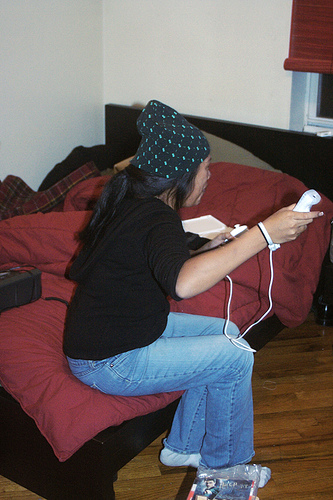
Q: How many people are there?
A: One.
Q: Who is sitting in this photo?
A: A woman.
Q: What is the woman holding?
A: Video game controllers.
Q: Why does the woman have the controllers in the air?
A: Because she is playing an interactive game.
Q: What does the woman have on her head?
A: A hat.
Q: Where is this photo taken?
A: In a bedroom.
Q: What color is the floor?
A: Brown.